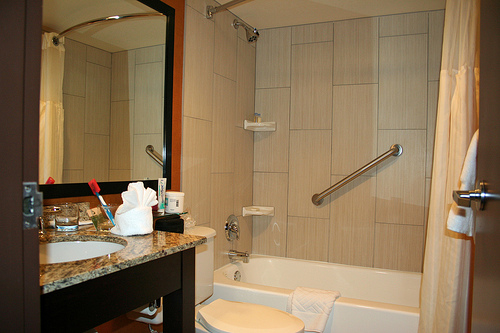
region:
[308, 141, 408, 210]
Metal rail bar on shower wall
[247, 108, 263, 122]
Bottle sitting on white shower shelf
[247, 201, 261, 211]
White soap sitting on shower shelf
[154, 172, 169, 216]
Toothpaste above toilet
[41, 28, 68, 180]
Reflection of shower curtain in mirror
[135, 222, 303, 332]
Toilet is white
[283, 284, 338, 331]
White towel next to toilet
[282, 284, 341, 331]
White towel on bath tub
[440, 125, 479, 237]
White towel next to shower curtain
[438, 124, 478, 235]
White towel next to door handle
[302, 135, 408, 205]
Metal rail bar against shower wall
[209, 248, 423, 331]
Bath tub is white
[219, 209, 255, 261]
Silver faucet below shower head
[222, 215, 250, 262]
Silver faucet above white bath tub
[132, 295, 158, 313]
White toilet paper roll next to toilet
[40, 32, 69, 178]
Reflection of curtain in mirror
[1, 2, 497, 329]
A bathroom with a tub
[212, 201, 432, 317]
A bathtub in a bathroom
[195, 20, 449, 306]
Shower in a bathroom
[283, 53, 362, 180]
Tile in a shower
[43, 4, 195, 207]
Mirror in a bathroom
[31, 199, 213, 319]
Sink in a bathroom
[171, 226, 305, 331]
Toilet in a bathroom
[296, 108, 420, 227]
Handrail in a shower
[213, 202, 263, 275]
Facuet in a bathtub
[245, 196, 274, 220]
Soap dish in a shower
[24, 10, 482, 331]
a bathroom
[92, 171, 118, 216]
a toothbrush in a glass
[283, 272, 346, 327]
a white towel on the edge of the bath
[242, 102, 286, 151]
a soap holder in the shower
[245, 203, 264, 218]
a bar of soap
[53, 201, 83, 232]
an empty glass on the counter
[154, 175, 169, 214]
a tube of toothpaste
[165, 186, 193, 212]
a wraped roll of toilet paper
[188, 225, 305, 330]
a beige toilet with the seat down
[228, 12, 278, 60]
a silver shower head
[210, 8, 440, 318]
hotel shower wide open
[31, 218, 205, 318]
granite topped bathroom vanity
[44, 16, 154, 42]
curved shower curtain holder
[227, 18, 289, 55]
chrome colored shower head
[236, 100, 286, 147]
shower supply wallholder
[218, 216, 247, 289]
chrome colored shower faucet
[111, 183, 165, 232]
hotel courtesy bathroom supplies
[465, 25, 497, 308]
bathroom brown colored door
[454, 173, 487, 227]
chrome colored bathroom door handle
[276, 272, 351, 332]
white colored bath mat